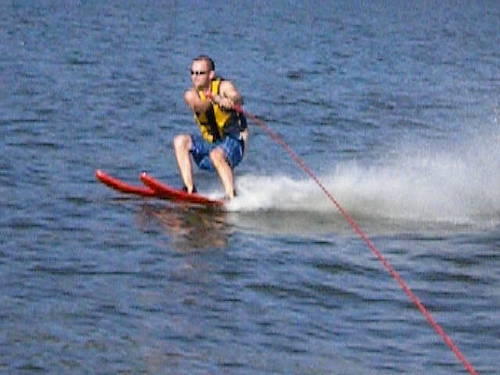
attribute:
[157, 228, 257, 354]
water — choppy blue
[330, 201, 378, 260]
rope — thin and red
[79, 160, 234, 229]
skis — red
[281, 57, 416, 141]
water — clear and blue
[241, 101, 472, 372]
rope — red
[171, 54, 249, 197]
man — young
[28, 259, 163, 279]
ripple — small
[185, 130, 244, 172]
shorts — blue, plaid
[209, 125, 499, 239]
water — white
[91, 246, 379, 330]
choppy water — choppy blue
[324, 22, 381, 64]
water — clear and blue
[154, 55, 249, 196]
man — water skiing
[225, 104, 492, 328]
rope — red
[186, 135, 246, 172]
short — blue and plaid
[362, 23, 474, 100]
water — choppy blue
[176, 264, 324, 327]
water — choppy blue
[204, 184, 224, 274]
ski boots — dark colored water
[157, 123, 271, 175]
shorts — paid